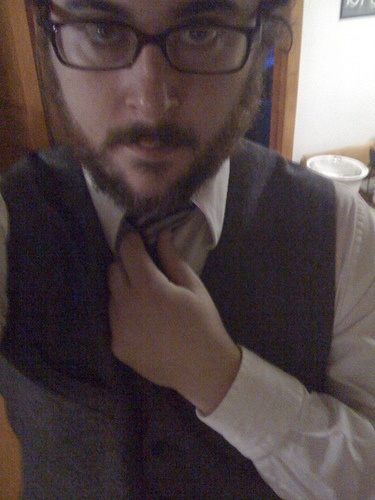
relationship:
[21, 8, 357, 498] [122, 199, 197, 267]
man wearing tie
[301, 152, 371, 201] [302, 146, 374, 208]
crockpot on table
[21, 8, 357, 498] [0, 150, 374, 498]
man wears shirt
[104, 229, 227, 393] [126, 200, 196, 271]
hand touching tie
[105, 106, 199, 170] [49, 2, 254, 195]
mustache on face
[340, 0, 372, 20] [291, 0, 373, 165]
mirror on wall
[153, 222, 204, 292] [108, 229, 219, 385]
thumb on hand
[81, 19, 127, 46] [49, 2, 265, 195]
eyeball on face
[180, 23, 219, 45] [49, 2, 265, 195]
eyeball on face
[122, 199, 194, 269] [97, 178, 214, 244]
tie on neck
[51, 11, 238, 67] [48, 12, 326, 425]
glasses on man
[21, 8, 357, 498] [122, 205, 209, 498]
man adjusting h tie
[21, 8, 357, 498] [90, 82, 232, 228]
man with beard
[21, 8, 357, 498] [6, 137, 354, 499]
man wearing vest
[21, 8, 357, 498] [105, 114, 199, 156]
man with a mustache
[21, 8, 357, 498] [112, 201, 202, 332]
man wearing tie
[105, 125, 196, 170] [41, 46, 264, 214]
mustache and beard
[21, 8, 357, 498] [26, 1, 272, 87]
man wearing glasses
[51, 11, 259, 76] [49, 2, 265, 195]
glasses on face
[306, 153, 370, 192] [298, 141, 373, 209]
cup on a desk